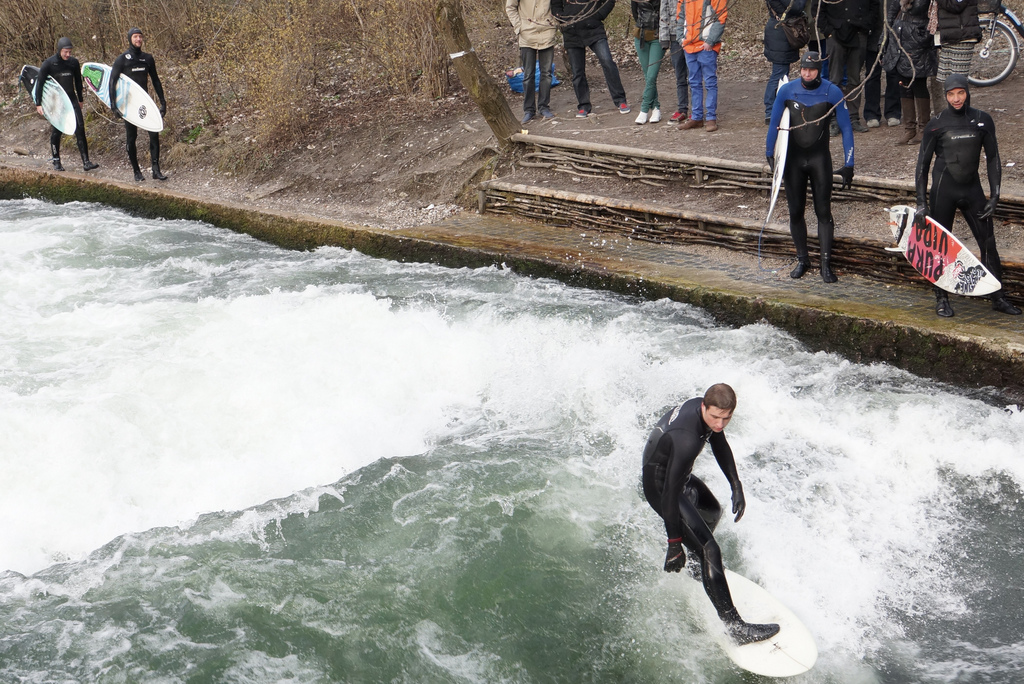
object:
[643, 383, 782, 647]
man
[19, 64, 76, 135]
surfboard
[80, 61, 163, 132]
surfboard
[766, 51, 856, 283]
wetsuit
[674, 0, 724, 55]
jacket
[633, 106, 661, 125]
shoes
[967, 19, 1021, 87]
wheel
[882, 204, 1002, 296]
surfboard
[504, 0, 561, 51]
jacket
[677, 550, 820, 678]
surfboard